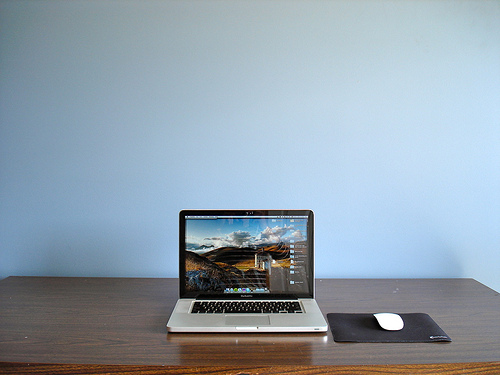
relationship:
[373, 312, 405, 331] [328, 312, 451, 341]
computer mouse and mouse pad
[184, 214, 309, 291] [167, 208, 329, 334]
screen of laptop computer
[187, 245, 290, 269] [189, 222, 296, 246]
mountains and clouds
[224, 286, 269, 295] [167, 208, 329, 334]
icons on laptop computer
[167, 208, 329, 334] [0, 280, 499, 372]
laptop computer on desk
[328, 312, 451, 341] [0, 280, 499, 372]
mouse pad on desk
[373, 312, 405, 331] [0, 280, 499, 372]
computer mouse on desk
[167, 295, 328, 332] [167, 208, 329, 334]
keyboard of laptop computer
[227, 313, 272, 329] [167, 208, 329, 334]
touch pad on laptop computer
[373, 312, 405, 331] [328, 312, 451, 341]
computer mouse on mouse pad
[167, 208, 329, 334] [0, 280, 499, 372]
laptop computer sitting on desk